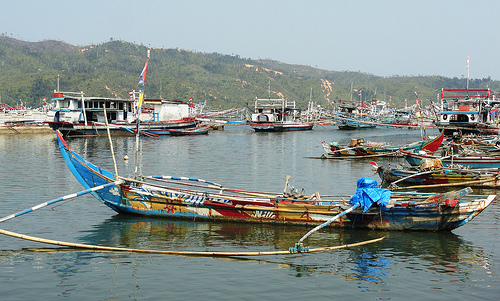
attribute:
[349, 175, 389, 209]
tarp — bright blue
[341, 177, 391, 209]
tarp — blue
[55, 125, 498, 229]
boat — small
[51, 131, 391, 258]
canoe — small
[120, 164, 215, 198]
stripes — blue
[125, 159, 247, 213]
stripes — blue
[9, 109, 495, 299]
water — large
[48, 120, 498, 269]
boat — large, white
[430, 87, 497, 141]
black and white boat — large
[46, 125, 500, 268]
colored boat — large, turquoise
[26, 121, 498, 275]
boat going down — white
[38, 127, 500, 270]
painted boat — colorful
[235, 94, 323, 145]
colorful boats — small, many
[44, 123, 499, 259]
hand-painted boat — small